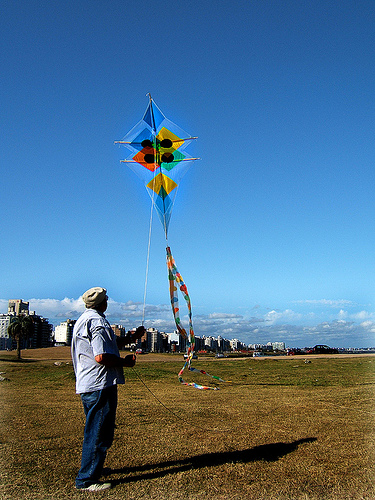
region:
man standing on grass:
[55, 278, 150, 489]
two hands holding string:
[124, 315, 150, 377]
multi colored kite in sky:
[111, 95, 205, 240]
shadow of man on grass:
[155, 431, 323, 480]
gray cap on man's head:
[78, 281, 111, 311]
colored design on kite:
[134, 129, 177, 171]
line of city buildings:
[133, 323, 230, 354]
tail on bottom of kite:
[154, 243, 231, 393]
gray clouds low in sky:
[227, 315, 322, 343]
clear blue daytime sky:
[208, 220, 278, 261]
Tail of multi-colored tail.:
[166, 244, 235, 392]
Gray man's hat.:
[79, 286, 109, 306]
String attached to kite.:
[128, 362, 299, 437]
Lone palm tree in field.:
[10, 313, 36, 363]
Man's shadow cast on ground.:
[112, 431, 318, 493]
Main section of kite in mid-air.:
[113, 89, 186, 242]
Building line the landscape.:
[4, 302, 306, 352]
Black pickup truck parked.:
[301, 343, 338, 352]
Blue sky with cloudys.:
[244, 298, 372, 343]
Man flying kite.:
[71, 287, 144, 492]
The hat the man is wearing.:
[83, 289, 104, 306]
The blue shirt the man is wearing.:
[72, 312, 126, 389]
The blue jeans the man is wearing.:
[70, 387, 112, 487]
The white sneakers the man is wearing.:
[79, 476, 110, 492]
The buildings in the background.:
[2, 294, 374, 356]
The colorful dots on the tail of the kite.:
[161, 251, 213, 394]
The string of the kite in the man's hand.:
[142, 212, 154, 357]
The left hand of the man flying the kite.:
[129, 320, 147, 335]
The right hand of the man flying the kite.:
[123, 350, 138, 367]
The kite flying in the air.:
[110, 81, 195, 249]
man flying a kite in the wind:
[61, 115, 217, 493]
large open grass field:
[239, 361, 374, 498]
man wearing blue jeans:
[61, 279, 140, 493]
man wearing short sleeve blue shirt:
[63, 278, 140, 493]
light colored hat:
[76, 277, 119, 316]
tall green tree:
[3, 308, 37, 369]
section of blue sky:
[205, 128, 371, 280]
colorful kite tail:
[155, 231, 216, 398]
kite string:
[126, 181, 157, 362]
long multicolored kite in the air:
[118, 91, 272, 397]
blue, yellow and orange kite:
[111, 92, 233, 390]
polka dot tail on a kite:
[165, 245, 233, 391]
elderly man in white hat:
[67, 285, 134, 488]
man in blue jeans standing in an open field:
[70, 286, 136, 491]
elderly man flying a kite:
[69, 90, 234, 490]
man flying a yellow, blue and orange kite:
[70, 92, 233, 491]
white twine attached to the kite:
[137, 165, 156, 341]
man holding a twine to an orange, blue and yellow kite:
[70, 188, 155, 490]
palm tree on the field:
[7, 312, 35, 359]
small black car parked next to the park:
[311, 343, 337, 353]